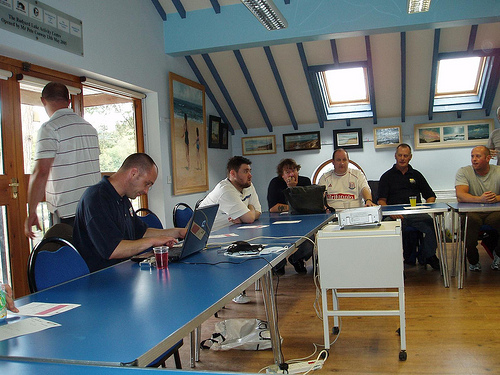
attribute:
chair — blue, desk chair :
[27, 224, 104, 291]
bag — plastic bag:
[199, 317, 284, 351]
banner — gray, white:
[2, 0, 87, 57]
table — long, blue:
[0, 202, 340, 367]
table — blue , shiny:
[47, 278, 155, 365]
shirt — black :
[377, 167, 434, 199]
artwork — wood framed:
[166, 68, 226, 212]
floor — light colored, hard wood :
[194, 251, 494, 373]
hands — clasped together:
[478, 185, 497, 207]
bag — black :
[281, 182, 336, 217]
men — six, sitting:
[16, 73, 126, 248]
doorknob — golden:
[8, 179, 18, 197]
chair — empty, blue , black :
[25, 237, 97, 290]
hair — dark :
[199, 148, 263, 229]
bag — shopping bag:
[206, 316, 285, 358]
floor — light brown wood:
[428, 293, 480, 372]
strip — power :
[261, 253, 351, 373]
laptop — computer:
[128, 200, 234, 263]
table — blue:
[6, 195, 347, 374]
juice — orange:
[408, 195, 431, 228]